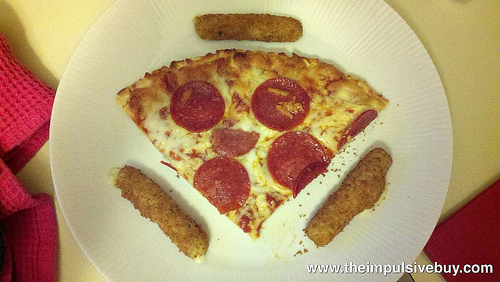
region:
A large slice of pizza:
[115, 48, 391, 238]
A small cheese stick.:
[107, 165, 209, 263]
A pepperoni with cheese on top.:
[251, 75, 311, 130]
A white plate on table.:
[48, 0, 454, 280]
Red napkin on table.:
[424, 177, 499, 281]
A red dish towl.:
[0, 29, 57, 281]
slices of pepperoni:
[160, 69, 370, 206]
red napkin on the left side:
[6, 48, 61, 277]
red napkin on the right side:
[425, 169, 498, 266]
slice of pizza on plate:
[116, 44, 378, 232]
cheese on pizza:
[142, 69, 385, 231]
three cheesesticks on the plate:
[108, 8, 390, 255]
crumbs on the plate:
[272, 137, 389, 264]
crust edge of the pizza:
[115, 50, 382, 104]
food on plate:
[41, 4, 461, 280]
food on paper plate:
[46, 1, 460, 279]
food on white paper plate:
[42, 0, 460, 280]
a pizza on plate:
[108, 45, 393, 245]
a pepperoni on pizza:
[166, 75, 228, 137]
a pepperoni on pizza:
[248, 73, 314, 133]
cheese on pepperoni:
[264, 82, 291, 99]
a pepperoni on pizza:
[204, 125, 262, 160]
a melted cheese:
[105, 165, 119, 185]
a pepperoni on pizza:
[334, 105, 381, 152]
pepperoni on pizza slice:
[167, 79, 226, 131]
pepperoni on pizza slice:
[250, 76, 308, 132]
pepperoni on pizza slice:
[336, 108, 377, 152]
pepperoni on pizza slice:
[291, 161, 325, 195]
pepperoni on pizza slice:
[265, 132, 322, 187]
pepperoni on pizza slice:
[210, 126, 261, 157]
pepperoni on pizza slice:
[190, 155, 252, 213]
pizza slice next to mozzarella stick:
[116, 50, 391, 237]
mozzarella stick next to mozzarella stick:
[107, 161, 210, 259]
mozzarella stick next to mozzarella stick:
[302, 146, 394, 246]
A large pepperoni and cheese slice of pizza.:
[115, 51, 390, 238]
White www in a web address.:
[305, 263, 341, 273]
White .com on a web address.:
[459, 262, 493, 273]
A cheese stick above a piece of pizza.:
[192, 12, 303, 43]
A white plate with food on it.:
[47, 2, 455, 280]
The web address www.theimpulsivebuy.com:
[305, 262, 492, 274]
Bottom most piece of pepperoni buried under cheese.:
[235, 193, 281, 234]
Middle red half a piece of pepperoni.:
[210, 125, 260, 157]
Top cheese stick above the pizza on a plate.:
[193, 12, 303, 43]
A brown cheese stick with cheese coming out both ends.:
[105, 162, 209, 262]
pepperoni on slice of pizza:
[170, 81, 226, 131]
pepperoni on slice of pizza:
[251, 78, 309, 131]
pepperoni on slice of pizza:
[210, 129, 260, 155]